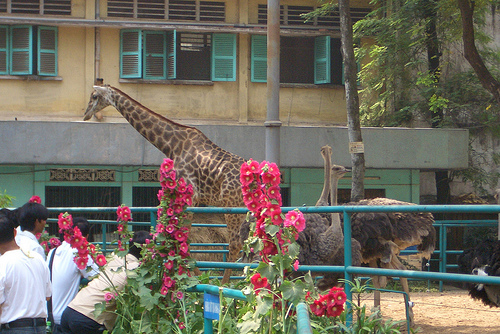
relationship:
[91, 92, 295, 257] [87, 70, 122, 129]
giraffe has head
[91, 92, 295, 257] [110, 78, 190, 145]
giraffe has mane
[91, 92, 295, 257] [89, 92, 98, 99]
giraffe has eye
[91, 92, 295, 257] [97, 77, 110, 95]
giraffe has ear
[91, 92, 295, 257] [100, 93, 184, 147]
giraffe has neck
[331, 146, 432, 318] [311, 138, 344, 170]
ostrich has head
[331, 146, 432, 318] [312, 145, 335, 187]
ostrich has neck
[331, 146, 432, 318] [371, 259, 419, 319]
ostrich has leg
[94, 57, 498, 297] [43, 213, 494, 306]
animals in cage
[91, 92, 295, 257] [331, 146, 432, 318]
giraffe near ostrich